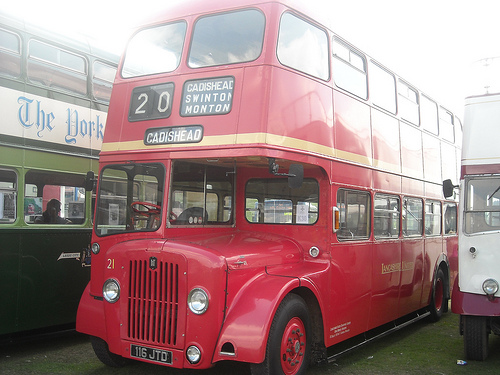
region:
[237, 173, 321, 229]
Small window on a bus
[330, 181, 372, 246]
Small window on a bus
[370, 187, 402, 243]
Small window on a bus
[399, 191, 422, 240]
Small window on a bus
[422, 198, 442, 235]
Small window on a bus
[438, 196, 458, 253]
Small window on a bus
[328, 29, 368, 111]
Small window on a bus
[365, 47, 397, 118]
Small window on a bus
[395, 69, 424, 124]
Small window on a bus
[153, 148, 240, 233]
Small window on a bus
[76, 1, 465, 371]
double decker red bus with gold trim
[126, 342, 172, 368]
black plate with white letters and numbers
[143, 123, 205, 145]
black destination sign with white letters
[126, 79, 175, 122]
black bus number sign with white numerals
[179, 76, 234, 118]
black route sign with white letters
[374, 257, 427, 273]
gold lettering on the side of the bus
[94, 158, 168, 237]
driver's front view window of a red bus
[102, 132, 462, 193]
gold trim at the bottom of the upper level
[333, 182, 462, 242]
side windows of the lower level of the bus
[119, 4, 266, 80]
front windows of the upper level of the bus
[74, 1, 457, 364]
red and yellow double decker bus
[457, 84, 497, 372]
white and red bus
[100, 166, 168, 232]
drivers window on right side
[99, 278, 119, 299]
driver's side headlight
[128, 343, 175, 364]
black and silver license plate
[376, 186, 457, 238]
passenger windows on side of bus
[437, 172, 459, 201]
a rear view mirror on side of bus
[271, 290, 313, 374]
black tire on red rim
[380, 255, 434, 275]
gold writing on side of bus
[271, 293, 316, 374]
The front tire of the bus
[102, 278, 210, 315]
Headlights on the bus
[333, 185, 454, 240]
Windows on the side of the bus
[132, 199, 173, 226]
A steering wheel in the bus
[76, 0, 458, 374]
A red bus between the other buses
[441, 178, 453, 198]
A mirror on the white bus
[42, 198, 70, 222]
A person sitting on the bus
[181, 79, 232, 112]
The destination of the bus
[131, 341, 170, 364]
The license plate on the bus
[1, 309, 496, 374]
The ground beneath the buses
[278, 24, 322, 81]
window on the bus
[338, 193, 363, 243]
window on the bus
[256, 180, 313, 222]
window on the bus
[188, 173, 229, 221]
window on the bus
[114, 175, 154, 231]
window on the bus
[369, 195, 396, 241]
window on the bus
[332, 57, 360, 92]
window on the bus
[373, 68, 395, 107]
window on the bus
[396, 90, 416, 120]
window on the bus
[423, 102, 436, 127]
window on the bus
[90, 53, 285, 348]
the front of a bus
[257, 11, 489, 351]
the side of a bus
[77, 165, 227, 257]
the windshield of a bus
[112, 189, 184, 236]
the steering wheel of a bus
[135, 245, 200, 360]
the grill of a bus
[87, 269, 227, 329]
the headlights of a bus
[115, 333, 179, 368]
the license plate of a bus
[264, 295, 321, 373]
the front wheel of a bus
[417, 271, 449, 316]
the back wheel of a bus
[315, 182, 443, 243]
the side windows of a bus